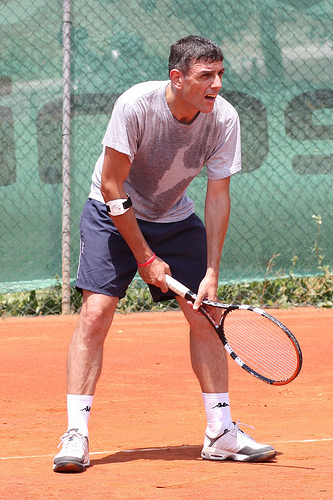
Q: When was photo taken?
A: Daytime.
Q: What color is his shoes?
A: White.